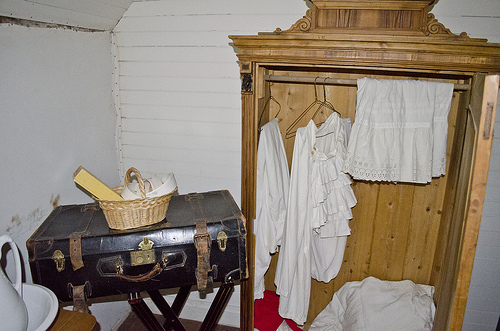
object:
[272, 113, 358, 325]
shirt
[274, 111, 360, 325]
clothes item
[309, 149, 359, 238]
lace trim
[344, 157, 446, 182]
lace trim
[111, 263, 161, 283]
handle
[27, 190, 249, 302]
suitcase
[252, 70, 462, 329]
clothing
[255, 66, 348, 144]
hanger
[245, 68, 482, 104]
pole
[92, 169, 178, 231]
basket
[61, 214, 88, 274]
strap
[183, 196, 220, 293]
strap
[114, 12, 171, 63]
board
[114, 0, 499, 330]
brick wall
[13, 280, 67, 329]
bowl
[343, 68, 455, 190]
cloth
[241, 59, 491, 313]
open door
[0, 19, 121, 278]
fabric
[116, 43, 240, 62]
board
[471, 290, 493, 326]
board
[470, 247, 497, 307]
wall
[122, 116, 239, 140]
board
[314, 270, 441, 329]
blanket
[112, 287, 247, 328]
stand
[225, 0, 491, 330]
closet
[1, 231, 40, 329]
basin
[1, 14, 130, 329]
wall